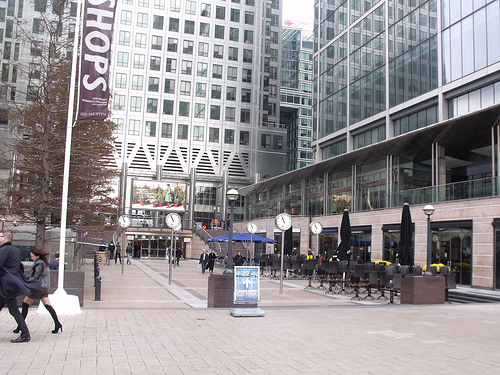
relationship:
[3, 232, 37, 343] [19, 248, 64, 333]
man walking with woman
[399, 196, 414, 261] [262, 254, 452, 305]
umbrella for seating area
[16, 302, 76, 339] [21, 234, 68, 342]
boots on woman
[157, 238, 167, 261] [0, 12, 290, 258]
door to building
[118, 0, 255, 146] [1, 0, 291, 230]
windows on building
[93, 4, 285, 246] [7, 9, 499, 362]
building in photo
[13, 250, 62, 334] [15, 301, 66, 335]
lady has boots